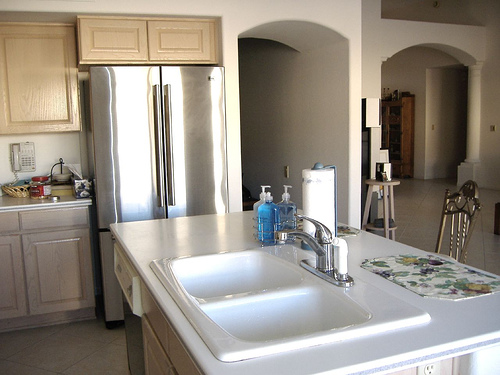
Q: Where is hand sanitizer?
A: By sink.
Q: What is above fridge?
A: Two small cabinets.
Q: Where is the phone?
A: On back wall.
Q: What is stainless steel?
A: Fridge and freezer.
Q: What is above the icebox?
A: A cabinet.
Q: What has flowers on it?
A: The place mat.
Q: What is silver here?
A: The icebox.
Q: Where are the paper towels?
A: On the counter.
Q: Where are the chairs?
A: By the counter.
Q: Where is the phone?
A: On the wall.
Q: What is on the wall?
A: A phone.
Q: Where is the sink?
A: On the counter.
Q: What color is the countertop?
A: White.